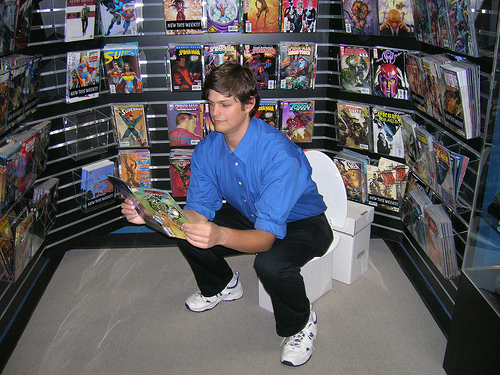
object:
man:
[121, 61, 335, 366]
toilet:
[253, 148, 376, 314]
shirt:
[181, 114, 329, 239]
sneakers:
[278, 308, 327, 367]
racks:
[0, 2, 489, 55]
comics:
[343, 1, 379, 36]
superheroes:
[375, 64, 401, 97]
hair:
[201, 62, 259, 113]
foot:
[281, 310, 317, 366]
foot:
[182, 272, 245, 314]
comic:
[104, 171, 191, 240]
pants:
[173, 197, 333, 335]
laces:
[278, 333, 317, 350]